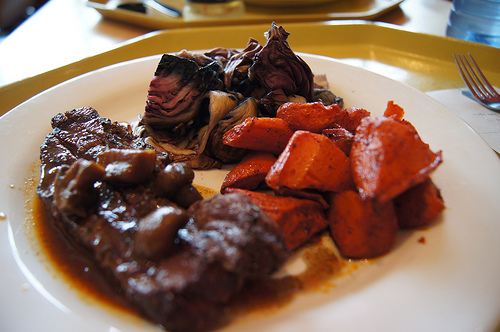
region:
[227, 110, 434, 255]
The carrots are roasted.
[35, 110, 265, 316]
The meat is cooked.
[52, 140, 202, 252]
The mushrooms look delicious.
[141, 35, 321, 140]
The cabbage is purple.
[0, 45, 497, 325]
The plate is white.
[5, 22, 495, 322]
The tray is gold.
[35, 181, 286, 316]
There is a glaze on the steak.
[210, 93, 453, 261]
The carrots are orange.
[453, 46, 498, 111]
There is a fork next to the plate.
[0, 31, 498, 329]
This is a really nice looking plate of food.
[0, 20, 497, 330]
food on a plate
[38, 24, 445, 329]
there are various food items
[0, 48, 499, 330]
the plate is white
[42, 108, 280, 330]
a piece of meat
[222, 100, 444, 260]
the yams are orange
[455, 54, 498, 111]
the fork is silver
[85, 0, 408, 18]
plate in the background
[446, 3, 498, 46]
there is a blue bottle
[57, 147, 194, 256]
mushrooms on the meat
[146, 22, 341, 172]
a weird looking food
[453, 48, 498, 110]
a fork right of the plate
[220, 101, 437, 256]
the carrots are orange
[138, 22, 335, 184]
cabbage on the plate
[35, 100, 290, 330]
meat on the plate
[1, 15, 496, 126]
a yellow tray under the plate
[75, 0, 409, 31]
another tray behind the first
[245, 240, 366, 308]
sauce on the plate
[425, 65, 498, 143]
a receipt under the fork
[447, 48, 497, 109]
the fork is metal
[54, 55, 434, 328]
The food on the plate.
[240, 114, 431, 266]
Orange veggies on the plate.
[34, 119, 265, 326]
Brown meat on the plate.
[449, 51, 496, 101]
Silver fork.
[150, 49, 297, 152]
The veggies on the plate.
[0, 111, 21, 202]
The piece of the white plate.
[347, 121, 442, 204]
The potato.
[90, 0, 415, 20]
The tray and the plate.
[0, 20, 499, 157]
a white plastic tray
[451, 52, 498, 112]
a silver fork on a tray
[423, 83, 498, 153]
a white paper receipt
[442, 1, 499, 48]
a plastic water bottle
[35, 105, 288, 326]
a steak on a plate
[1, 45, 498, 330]
a white ceramic plate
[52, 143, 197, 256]
some mushrooms on a steak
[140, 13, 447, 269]
some vegetables on a plate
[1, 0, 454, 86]
A long table